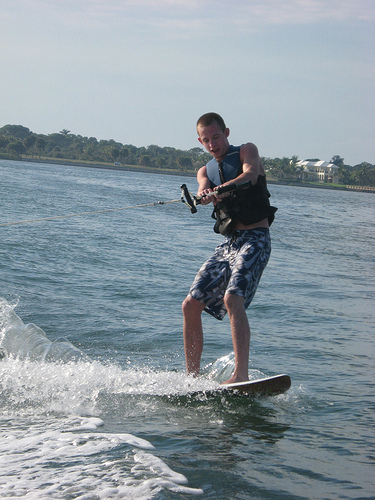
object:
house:
[288, 157, 342, 184]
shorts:
[187, 226, 273, 320]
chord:
[141, 200, 166, 207]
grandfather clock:
[180, 108, 267, 237]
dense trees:
[13, 117, 124, 164]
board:
[130, 373, 291, 405]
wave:
[14, 356, 143, 423]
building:
[283, 153, 349, 184]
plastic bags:
[6, 325, 125, 416]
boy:
[180, 111, 277, 389]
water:
[0, 157, 372, 498]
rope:
[0, 190, 215, 226]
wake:
[147, 105, 242, 181]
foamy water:
[15, 435, 164, 493]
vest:
[201, 144, 280, 238]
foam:
[0, 287, 334, 499]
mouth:
[209, 147, 220, 155]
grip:
[181, 179, 254, 215]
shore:
[0, 147, 374, 192]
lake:
[1, 160, 373, 498]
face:
[196, 120, 225, 158]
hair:
[196, 112, 226, 137]